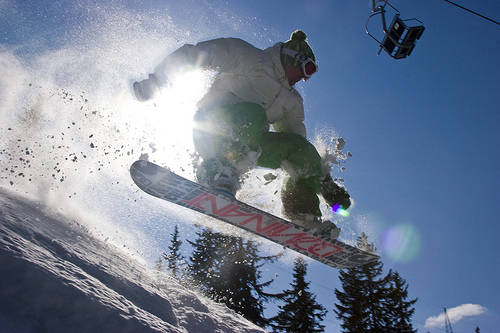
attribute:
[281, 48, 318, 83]
goggles — white, red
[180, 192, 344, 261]
writing — red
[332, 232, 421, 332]
tree — green, tall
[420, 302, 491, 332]
cloud — white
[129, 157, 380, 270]
snowboard — long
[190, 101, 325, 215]
pants — green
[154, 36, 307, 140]
jacket — white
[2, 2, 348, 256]
snow — up in the air, white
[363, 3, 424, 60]
ski lift chair — metal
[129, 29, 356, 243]
snowboarder — jumping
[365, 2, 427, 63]
ski lift — metal, moving overhead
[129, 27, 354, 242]
man — snowboarding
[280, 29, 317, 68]
beanie — green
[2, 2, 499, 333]
sky — clear, cloudless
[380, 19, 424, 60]
bench — black